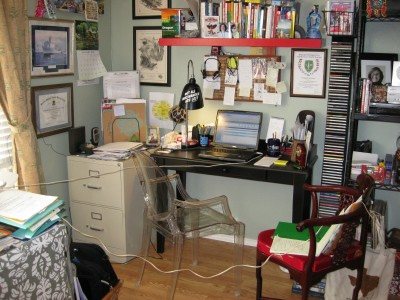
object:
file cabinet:
[65, 141, 155, 263]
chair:
[131, 153, 245, 298]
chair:
[254, 166, 374, 300]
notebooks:
[268, 222, 331, 257]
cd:
[328, 90, 348, 105]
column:
[314, 6, 360, 226]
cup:
[267, 137, 281, 157]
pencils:
[272, 133, 274, 140]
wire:
[15, 153, 266, 188]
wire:
[60, 215, 323, 279]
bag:
[324, 199, 397, 300]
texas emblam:
[347, 268, 379, 297]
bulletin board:
[204, 56, 282, 105]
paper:
[235, 59, 254, 87]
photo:
[148, 129, 156, 142]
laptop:
[199, 108, 264, 163]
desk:
[153, 131, 313, 279]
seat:
[258, 224, 362, 268]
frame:
[145, 125, 161, 146]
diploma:
[38, 91, 68, 131]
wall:
[19, 3, 129, 202]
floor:
[96, 233, 328, 300]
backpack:
[67, 240, 120, 300]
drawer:
[184, 158, 267, 187]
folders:
[0, 189, 69, 240]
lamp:
[180, 59, 204, 149]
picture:
[29, 24, 70, 72]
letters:
[181, 90, 198, 103]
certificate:
[296, 53, 322, 92]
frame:
[287, 47, 325, 100]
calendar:
[74, 18, 108, 86]